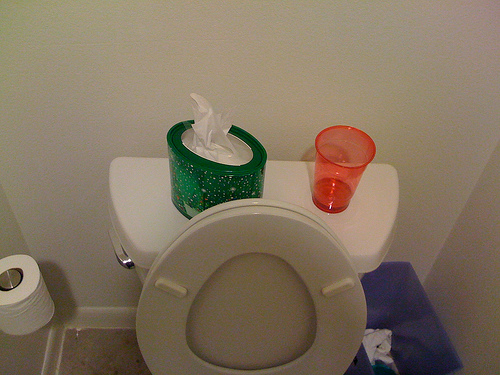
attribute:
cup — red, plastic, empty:
[301, 124, 378, 221]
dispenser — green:
[158, 120, 269, 224]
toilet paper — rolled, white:
[0, 250, 55, 343]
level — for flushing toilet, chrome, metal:
[105, 223, 136, 272]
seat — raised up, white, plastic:
[127, 188, 374, 375]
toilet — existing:
[102, 148, 407, 374]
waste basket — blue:
[343, 248, 468, 374]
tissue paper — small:
[178, 90, 256, 167]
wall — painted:
[2, 3, 499, 344]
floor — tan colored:
[52, 321, 145, 374]